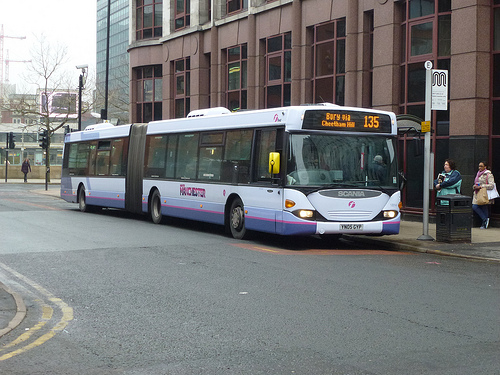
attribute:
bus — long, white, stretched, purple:
[57, 100, 402, 246]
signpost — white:
[421, 57, 452, 242]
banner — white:
[431, 69, 450, 113]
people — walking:
[436, 159, 500, 227]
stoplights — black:
[35, 126, 53, 191]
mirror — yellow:
[266, 150, 283, 184]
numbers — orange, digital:
[362, 113, 382, 132]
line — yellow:
[1, 262, 75, 368]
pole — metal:
[422, 59, 435, 243]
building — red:
[132, 1, 497, 221]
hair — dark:
[444, 156, 457, 173]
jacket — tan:
[470, 172, 499, 207]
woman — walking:
[19, 157, 32, 183]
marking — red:
[233, 239, 424, 258]